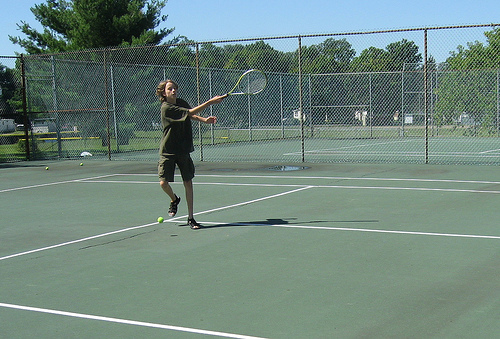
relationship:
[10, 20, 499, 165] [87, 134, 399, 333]
fence on court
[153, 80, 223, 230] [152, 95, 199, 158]
boy wearing shirt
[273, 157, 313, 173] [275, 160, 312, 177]
water in puddle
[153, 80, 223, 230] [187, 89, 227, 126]
boy has arms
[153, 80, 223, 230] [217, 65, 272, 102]
boy hold racket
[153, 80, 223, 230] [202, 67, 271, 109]
boy holds racket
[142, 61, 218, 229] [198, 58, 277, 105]
boy holds racket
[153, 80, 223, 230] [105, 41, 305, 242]
boy plays tennis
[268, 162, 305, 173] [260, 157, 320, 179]
waterpuddle on tennis court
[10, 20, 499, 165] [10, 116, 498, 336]
fence divide tennis court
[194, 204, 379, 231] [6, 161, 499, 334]
shadow on tennis court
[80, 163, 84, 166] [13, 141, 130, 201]
tennis ball on ground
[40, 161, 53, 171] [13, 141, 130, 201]
tennis ball on ground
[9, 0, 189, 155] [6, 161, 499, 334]
tree behind tennis court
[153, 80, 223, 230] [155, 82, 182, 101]
boy has face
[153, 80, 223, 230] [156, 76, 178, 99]
boy has hair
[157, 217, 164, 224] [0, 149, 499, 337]
tennis on court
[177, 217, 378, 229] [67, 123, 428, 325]
shadow on tennis court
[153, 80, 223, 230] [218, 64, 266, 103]
boy holding racket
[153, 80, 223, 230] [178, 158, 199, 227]
boy has leg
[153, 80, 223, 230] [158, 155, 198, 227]
boy has leg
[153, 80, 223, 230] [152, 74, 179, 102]
boy has head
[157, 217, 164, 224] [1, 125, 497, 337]
tennis on ground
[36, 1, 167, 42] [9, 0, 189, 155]
leaves on tree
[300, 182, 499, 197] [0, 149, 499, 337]
line on court